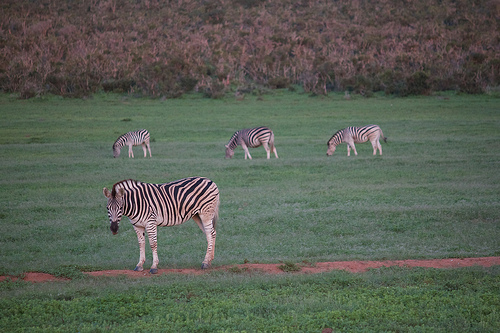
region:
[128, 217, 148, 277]
leg of small zebra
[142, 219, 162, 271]
leg of small zebra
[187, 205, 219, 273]
leg of small zebra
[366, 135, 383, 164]
leg of small zebra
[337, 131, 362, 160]
leg of small zebra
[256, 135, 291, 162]
leg of small zebra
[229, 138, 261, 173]
leg of small zebra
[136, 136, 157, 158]
leg of small zebra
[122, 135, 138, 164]
leg of small zebra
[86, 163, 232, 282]
black and white zebra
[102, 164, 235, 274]
zebra in the grass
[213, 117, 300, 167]
zebra in the grass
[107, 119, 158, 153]
zebra in the grass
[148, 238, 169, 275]
leg of the zebra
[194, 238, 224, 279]
leg of the zebra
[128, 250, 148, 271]
leg of the zebra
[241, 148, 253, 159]
leg of the zebra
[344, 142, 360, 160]
leg of the zebra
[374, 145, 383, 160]
leg of the zebra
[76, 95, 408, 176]
three zebras are eating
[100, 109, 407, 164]
three zebras are eating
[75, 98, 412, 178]
three zebras are eating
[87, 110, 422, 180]
three zebras are eating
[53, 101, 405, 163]
three zebras are eating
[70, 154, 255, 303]
the zebra is watching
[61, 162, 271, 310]
the zebra is watching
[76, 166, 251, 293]
the zebra is watching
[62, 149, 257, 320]
the zebra is watching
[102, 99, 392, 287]
a group of zebras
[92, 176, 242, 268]
stripes on the zebra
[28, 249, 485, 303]
trail in the field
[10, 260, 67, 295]
a patch of dirt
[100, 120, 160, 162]
the zebra is eating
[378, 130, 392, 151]
tail of the zebra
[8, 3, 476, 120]
a field of bushes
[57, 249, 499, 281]
the trail is brown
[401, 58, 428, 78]
leaves on the tree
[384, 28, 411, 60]
leaves on the tree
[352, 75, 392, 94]
leaves on the tree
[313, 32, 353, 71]
leaves on the tree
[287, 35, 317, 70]
leaves on the tree